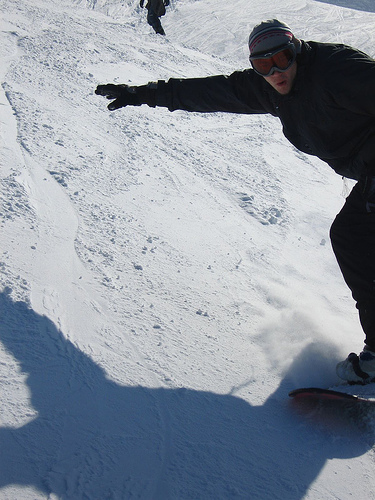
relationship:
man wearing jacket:
[218, 20, 345, 128] [291, 80, 355, 162]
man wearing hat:
[94, 16, 374, 386] [246, 16, 303, 56]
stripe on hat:
[249, 28, 293, 53] [245, 14, 299, 53]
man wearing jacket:
[94, 16, 374, 386] [143, 37, 374, 182]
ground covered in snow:
[25, 18, 331, 294] [189, 162, 304, 267]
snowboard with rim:
[288, 380, 373, 402] [276, 376, 373, 408]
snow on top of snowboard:
[285, 348, 373, 409] [281, 380, 374, 413]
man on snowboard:
[94, 16, 374, 386] [278, 372, 361, 418]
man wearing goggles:
[94, 16, 374, 386] [247, 40, 302, 78]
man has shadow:
[138, 0, 172, 36] [2, 291, 373, 495]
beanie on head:
[244, 27, 294, 55] [248, 19, 301, 95]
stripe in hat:
[244, 28, 297, 42] [244, 16, 297, 50]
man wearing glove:
[164, 33, 355, 408] [88, 77, 163, 109]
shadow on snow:
[2, 291, 373, 495] [4, 3, 370, 499]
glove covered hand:
[93, 82, 154, 113] [92, 69, 136, 114]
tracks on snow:
[149, 194, 288, 331] [4, 3, 370, 499]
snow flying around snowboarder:
[251, 280, 346, 381] [285, 376, 373, 411]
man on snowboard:
[94, 16, 374, 386] [299, 351, 366, 427]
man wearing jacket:
[201, 36, 351, 345] [162, 67, 368, 174]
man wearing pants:
[94, 16, 374, 386] [328, 177, 374, 353]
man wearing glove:
[94, 16, 374, 386] [87, 72, 160, 119]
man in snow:
[94, 16, 374, 386] [146, 282, 290, 395]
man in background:
[138, 0, 172, 36] [27, 7, 183, 69]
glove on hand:
[93, 82, 154, 113] [77, 62, 145, 110]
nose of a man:
[263, 69, 283, 90] [97, 17, 373, 415]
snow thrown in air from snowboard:
[251, 280, 346, 381] [265, 364, 367, 420]